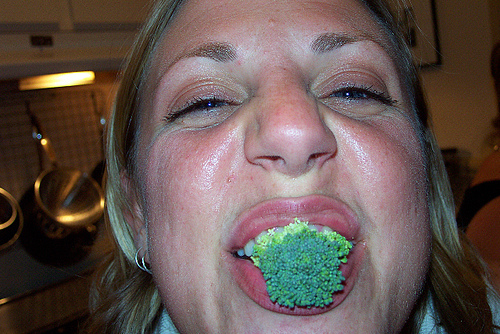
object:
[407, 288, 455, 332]
white collar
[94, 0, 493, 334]
hair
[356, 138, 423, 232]
cheek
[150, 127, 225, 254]
cheek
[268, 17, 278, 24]
pimple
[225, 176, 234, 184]
pimple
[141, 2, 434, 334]
face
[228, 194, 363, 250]
lip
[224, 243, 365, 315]
lip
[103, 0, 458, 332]
girl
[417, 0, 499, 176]
wall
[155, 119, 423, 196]
acne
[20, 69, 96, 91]
light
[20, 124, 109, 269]
cooking tools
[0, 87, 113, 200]
peg board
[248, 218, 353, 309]
broccoli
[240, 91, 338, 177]
nose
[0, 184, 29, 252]
pots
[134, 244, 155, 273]
earring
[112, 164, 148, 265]
ear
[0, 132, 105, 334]
back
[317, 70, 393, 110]
eye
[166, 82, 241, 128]
eye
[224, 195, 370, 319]
girl's mouth